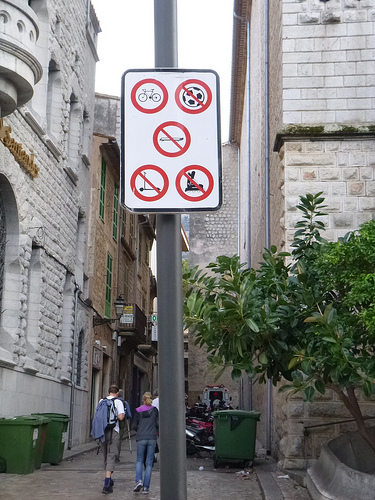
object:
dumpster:
[208, 406, 262, 469]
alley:
[10, 426, 264, 498]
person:
[92, 383, 129, 493]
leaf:
[245, 318, 261, 333]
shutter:
[98, 154, 107, 223]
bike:
[185, 408, 215, 459]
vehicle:
[197, 382, 235, 410]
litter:
[235, 468, 250, 477]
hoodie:
[131, 404, 160, 442]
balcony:
[117, 300, 148, 346]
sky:
[92, 0, 234, 145]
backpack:
[99, 395, 118, 425]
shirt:
[98, 396, 125, 434]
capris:
[100, 430, 120, 471]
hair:
[143, 391, 153, 406]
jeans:
[135, 439, 157, 486]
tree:
[182, 191, 375, 447]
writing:
[0, 115, 40, 180]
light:
[114, 295, 126, 319]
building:
[91, 92, 158, 440]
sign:
[118, 68, 223, 214]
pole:
[155, 212, 187, 499]